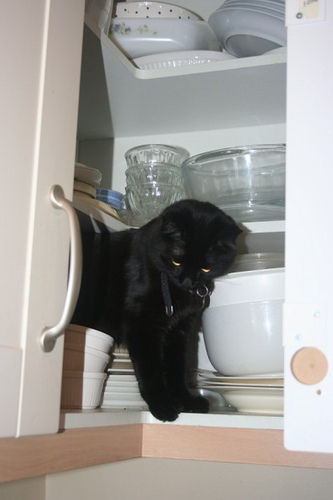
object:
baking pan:
[110, 16, 218, 56]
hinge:
[289, 341, 327, 388]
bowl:
[122, 178, 188, 216]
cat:
[81, 175, 278, 452]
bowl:
[125, 160, 185, 186]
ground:
[135, 57, 249, 110]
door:
[0, 0, 84, 437]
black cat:
[70, 199, 245, 421]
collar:
[158, 270, 209, 316]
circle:
[279, 337, 331, 399]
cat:
[58, 193, 252, 427]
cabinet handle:
[44, 183, 84, 353]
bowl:
[181, 142, 286, 207]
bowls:
[204, 7, 256, 43]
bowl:
[64, 324, 114, 352]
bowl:
[65, 342, 110, 374]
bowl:
[63, 373, 110, 412]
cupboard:
[1, 6, 86, 481]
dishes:
[208, 0, 291, 60]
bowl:
[122, 142, 190, 167]